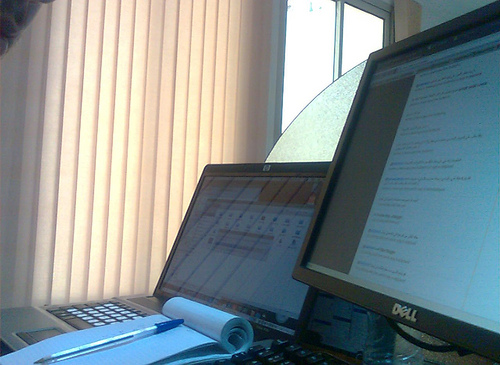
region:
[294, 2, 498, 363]
black Dell computer monitor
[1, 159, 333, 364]
silver HP laptop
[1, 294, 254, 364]
white note pad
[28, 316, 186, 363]
clear with a blue cap pen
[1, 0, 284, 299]
white window blinds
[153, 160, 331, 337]
laptop screen with lots of icons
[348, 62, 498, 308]
writing on a computer screen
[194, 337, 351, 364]
black key board keys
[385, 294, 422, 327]
Computer makers logo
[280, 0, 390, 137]
bright sunlight in a window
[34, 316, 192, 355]
The pen on the notepad.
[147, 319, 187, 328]
The blue cap of the pen.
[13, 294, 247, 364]
The notepad on the laptop.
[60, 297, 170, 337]
The keyboard of the laptop.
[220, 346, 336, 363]
The keyboard of the computer.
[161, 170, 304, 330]
The screen of the laptop.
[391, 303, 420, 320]
The word Dell on the computer monitor.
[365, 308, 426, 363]
The plastic bottle behind the computer monitor.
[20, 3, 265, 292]
The blinds on the window.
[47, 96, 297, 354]
a laptop on a table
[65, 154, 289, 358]
a laptop that is open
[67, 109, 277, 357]
a laptop that is turned on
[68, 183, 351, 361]
a notepad on a laptop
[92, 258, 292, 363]
notepad on a computer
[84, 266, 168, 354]
a blue pen on a notepad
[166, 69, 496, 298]
a table with laptop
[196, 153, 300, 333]
the screen of a laptop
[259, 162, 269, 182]
the webcam of a laptop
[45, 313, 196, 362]
a small ball point pen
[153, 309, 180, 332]
the cap of a pen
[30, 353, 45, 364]
the tip of a pen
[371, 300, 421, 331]
the logo of a computer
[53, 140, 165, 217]
the shades on a window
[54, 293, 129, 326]
the keys of a keyboard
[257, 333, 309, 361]
an external keyboard for a computer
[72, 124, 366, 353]
view in a study roomn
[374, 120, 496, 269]
the computer is open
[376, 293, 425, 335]
words are written in grey color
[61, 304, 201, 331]
pen is on the papers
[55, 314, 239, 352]
the pages are white in color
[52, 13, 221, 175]
the wall is white in color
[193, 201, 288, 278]
the words are wruitten in blue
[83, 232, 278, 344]
the laptop is open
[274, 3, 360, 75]
the window is closed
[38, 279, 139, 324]
the laptop is gery in color